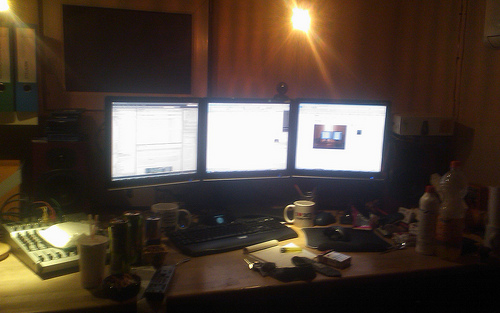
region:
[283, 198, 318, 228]
white coffee mug on desk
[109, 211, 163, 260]
soda cans on desk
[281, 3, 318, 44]
light hanging on wall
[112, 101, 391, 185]
computer monitors on desk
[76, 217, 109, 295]
white foam cup with straw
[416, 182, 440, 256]
hair spray can on desk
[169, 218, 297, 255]
black computer keyboard on desk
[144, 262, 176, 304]
black television remote control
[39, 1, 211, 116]
flat screen television on table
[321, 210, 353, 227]
black sunglasses on desk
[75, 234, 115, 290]
the cup is white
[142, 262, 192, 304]
remote is on table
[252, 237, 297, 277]
the pad is open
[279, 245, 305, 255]
the lighter is yellow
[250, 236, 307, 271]
lighter is on the pad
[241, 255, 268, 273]
keys on the table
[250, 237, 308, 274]
keys beside the pad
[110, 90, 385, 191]
three monitors on table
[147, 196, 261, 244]
mug is behind keyboard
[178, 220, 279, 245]
the keyboard is black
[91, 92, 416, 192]
three computer monitors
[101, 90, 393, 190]
the computers are on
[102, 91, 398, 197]
the three computers are turned on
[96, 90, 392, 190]
the three monitors are attached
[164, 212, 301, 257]
one keyboard is on the desk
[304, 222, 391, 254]
a black mouse on a pad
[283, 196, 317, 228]
a white coffee cup is on the desk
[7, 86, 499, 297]
the monitors are on a desk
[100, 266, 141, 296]
an ashtray is on the desk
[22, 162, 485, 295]
the desk is cluttered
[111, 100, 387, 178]
these are three monitors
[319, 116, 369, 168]
the monitor is on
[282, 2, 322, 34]
the light is on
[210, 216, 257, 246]
this is a keyboard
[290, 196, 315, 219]
this is a cup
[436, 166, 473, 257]
the bottle is big in size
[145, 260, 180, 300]
this is a remote control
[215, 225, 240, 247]
the keyboard is black in color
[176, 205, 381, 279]
the table is full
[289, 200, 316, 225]
the cup is white in color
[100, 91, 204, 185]
Monitor one of a three monitor array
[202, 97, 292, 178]
Monitor two of a three monitor array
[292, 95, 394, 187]
Monitor three of a three monitor array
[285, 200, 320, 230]
Coffee cup sitting on a table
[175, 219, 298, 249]
Computer keyboard sitting on a table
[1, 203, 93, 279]
Mixer sitting on a table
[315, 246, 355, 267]
Pack of cigarettes sitting on a table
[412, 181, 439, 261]
Compressed air for cleaning computer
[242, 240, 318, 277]
Notepad sitting on a table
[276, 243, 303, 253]
Lighter sitting on a notepad